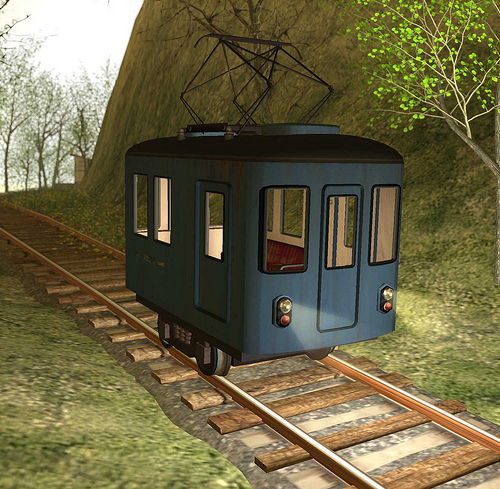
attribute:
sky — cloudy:
[1, 0, 142, 193]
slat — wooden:
[178, 352, 379, 416]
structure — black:
[173, 27, 336, 130]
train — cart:
[133, 129, 443, 409]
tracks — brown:
[157, 362, 499, 486]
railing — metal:
[277, 255, 309, 274]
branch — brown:
[440, 70, 480, 131]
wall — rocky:
[82, 4, 454, 201]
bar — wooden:
[226, 399, 471, 480]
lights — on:
[272, 284, 393, 326]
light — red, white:
[278, 273, 342, 298]